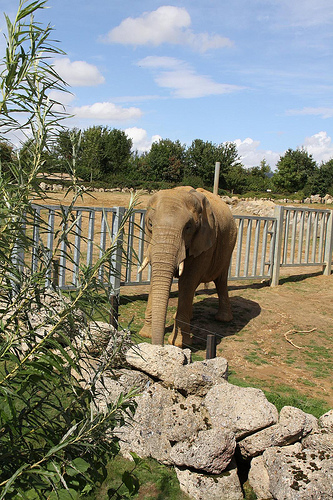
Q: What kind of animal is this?
A: Elephant.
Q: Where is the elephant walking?
A: Dirt patch.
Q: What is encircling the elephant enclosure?
A: Fence.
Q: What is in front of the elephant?
A: Rocks.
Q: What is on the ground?
A: Grass.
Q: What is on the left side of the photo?
A: Brush and foliage.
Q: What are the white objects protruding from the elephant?
A: Tusks.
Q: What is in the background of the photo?
A: Tall trees.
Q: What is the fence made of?
A: Metal.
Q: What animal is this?
A: Elephant.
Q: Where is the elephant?
A: In front of the fence.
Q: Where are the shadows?
A: On the ground.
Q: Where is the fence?
A: Behind the elephant.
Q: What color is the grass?
A: Brown.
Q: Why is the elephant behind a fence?
A: So it does not escape.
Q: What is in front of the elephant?
A: A pile of rocks.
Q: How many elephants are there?
A: One.